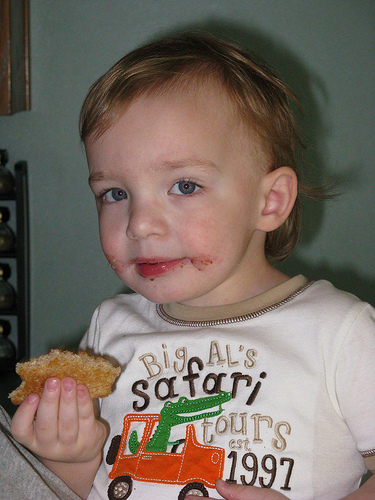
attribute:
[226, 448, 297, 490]
date — 1997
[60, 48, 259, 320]
face —  child's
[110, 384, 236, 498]
truck — red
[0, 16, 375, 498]
child — hungry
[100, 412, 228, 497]
truck — red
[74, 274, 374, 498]
shirt — white,  CHILD'S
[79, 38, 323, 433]
child —  HUNGRY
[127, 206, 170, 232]
nose —  child's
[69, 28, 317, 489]
child — hungry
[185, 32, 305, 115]
cowlick —   red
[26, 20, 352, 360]
child —  HUNGRY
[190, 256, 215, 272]
food —  Some